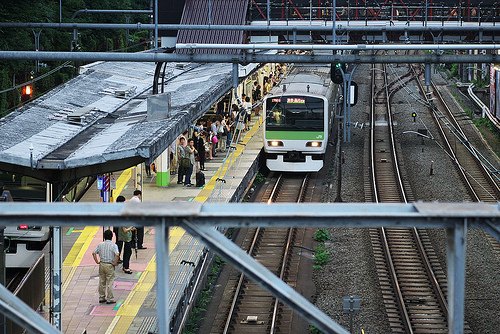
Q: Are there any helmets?
A: No, there are no helmets.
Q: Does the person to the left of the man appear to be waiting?
A: Yes, the person is waiting.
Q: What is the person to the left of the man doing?
A: The person is waiting.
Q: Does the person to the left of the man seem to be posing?
A: No, the person is waiting.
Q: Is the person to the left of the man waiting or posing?
A: The person is waiting.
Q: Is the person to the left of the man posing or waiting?
A: The person is waiting.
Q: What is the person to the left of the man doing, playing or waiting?
A: The person is waiting.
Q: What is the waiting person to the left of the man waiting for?
A: The person is waiting for the train.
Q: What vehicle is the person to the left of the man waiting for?
A: The person is waiting for the train.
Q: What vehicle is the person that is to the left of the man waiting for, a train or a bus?
A: The person is waiting for a train.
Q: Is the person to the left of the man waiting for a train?
A: Yes, the person is waiting for a train.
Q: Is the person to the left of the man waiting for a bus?
A: No, the person is waiting for a train.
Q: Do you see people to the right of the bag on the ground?
A: No, the person is to the left of the bag.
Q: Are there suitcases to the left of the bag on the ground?
A: No, there is a person to the left of the bag.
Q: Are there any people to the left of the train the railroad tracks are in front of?
A: Yes, there is a person to the left of the train.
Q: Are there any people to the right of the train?
A: No, the person is to the left of the train.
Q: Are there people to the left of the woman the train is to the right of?
A: Yes, there is a person to the left of the woman.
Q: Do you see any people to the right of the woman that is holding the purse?
A: No, the person is to the left of the woman.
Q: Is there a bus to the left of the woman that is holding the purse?
A: No, there is a person to the left of the woman.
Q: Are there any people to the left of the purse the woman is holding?
A: Yes, there is a person to the left of the purse.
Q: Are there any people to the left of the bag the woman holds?
A: Yes, there is a person to the left of the purse.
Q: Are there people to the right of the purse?
A: No, the person is to the left of the purse.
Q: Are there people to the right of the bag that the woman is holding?
A: No, the person is to the left of the purse.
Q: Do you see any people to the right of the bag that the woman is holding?
A: No, the person is to the left of the purse.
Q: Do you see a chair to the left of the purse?
A: No, there is a person to the left of the purse.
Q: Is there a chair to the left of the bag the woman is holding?
A: No, there is a person to the left of the purse.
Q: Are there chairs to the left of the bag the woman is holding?
A: No, there is a person to the left of the purse.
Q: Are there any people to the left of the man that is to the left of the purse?
A: Yes, there is a person to the left of the man.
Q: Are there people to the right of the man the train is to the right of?
A: No, the person is to the left of the man.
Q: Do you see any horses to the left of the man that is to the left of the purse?
A: No, there is a person to the left of the man.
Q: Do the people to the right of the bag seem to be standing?
A: Yes, the people are standing.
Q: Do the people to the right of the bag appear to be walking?
A: No, the people are standing.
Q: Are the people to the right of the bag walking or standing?
A: The people are standing.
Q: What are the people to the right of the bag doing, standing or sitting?
A: The people are standing.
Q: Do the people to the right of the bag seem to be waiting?
A: Yes, the people are waiting.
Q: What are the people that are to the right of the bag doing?
A: The people are waiting.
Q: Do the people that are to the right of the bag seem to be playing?
A: No, the people are waiting.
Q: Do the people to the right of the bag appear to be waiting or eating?
A: The people are waiting.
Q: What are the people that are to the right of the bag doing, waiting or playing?
A: The people are waiting.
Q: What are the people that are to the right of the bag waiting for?
A: The people are waiting for the train.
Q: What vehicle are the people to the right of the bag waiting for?
A: The people are waiting for the train.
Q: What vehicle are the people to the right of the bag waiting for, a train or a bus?
A: The people are waiting for a train.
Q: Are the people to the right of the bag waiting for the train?
A: Yes, the people are waiting for the train.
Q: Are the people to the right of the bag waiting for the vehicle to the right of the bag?
A: Yes, the people are waiting for the train.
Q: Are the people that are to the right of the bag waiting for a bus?
A: No, the people are waiting for the train.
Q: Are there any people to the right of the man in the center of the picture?
A: Yes, there are people to the right of the man.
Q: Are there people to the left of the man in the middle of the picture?
A: No, the people are to the right of the man.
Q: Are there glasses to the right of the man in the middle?
A: No, there are people to the right of the man.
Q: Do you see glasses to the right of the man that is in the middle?
A: No, there are people to the right of the man.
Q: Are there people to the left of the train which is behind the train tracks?
A: Yes, there are people to the left of the train.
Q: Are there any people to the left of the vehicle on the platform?
A: Yes, there are people to the left of the train.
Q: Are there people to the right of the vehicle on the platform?
A: No, the people are to the left of the train.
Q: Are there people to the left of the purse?
A: Yes, there are people to the left of the purse.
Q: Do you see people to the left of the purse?
A: Yes, there are people to the left of the purse.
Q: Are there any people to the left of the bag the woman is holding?
A: Yes, there are people to the left of the purse.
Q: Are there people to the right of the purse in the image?
A: No, the people are to the left of the purse.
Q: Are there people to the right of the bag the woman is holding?
A: No, the people are to the left of the purse.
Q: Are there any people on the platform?
A: Yes, there are people on the platform.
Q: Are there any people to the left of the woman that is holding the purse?
A: Yes, there are people to the left of the woman.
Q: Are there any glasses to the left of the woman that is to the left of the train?
A: No, there are people to the left of the woman.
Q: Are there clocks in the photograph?
A: No, there are no clocks.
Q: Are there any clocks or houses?
A: No, there are no clocks or houses.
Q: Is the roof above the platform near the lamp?
A: Yes, the roof is above the platform.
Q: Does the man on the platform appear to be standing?
A: Yes, the man is standing.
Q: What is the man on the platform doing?
A: The man is standing.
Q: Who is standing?
A: The man is standing.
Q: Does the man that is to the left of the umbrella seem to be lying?
A: No, the man is standing.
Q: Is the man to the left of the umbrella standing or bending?
A: The man is standing.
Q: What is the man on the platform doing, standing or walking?
A: The man is standing.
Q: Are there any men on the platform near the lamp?
A: Yes, there is a man on the platform.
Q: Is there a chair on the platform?
A: No, there is a man on the platform.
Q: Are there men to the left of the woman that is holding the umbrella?
A: Yes, there is a man to the left of the woman.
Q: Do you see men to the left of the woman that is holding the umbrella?
A: Yes, there is a man to the left of the woman.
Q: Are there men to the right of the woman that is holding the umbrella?
A: No, the man is to the left of the woman.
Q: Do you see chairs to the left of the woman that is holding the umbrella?
A: No, there is a man to the left of the woman.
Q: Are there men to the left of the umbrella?
A: Yes, there is a man to the left of the umbrella.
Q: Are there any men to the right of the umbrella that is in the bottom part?
A: No, the man is to the left of the umbrella.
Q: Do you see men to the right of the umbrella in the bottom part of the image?
A: No, the man is to the left of the umbrella.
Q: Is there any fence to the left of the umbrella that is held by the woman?
A: No, there is a man to the left of the umbrella.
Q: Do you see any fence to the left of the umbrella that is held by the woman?
A: No, there is a man to the left of the umbrella.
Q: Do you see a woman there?
A: Yes, there is a woman.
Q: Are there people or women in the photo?
A: Yes, there is a woman.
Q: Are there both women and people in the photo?
A: Yes, there are both a woman and people.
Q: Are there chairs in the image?
A: No, there are no chairs.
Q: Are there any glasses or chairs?
A: No, there are no chairs or glasses.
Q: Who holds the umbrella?
A: The woman holds the umbrella.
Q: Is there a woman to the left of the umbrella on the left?
A: Yes, there is a woman to the left of the umbrella.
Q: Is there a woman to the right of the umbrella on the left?
A: No, the woman is to the left of the umbrella.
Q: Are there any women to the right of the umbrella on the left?
A: No, the woman is to the left of the umbrella.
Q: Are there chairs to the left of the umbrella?
A: No, there is a woman to the left of the umbrella.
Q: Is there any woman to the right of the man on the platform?
A: Yes, there is a woman to the right of the man.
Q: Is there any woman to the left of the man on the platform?
A: No, the woman is to the right of the man.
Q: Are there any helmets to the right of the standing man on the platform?
A: No, there is a woman to the right of the man.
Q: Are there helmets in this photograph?
A: No, there are no helmets.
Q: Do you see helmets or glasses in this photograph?
A: No, there are no helmets or glasses.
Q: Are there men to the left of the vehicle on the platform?
A: Yes, there is a man to the left of the train.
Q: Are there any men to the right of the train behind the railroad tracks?
A: No, the man is to the left of the train.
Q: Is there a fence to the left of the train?
A: No, there is a man to the left of the train.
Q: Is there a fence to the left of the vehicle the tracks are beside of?
A: No, there is a man to the left of the train.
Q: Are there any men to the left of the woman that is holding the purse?
A: Yes, there is a man to the left of the woman.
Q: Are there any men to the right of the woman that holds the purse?
A: No, the man is to the left of the woman.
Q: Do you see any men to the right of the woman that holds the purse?
A: No, the man is to the left of the woman.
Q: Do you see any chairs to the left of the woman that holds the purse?
A: No, there is a man to the left of the woman.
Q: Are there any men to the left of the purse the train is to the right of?
A: Yes, there is a man to the left of the purse.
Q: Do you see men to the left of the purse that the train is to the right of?
A: Yes, there is a man to the left of the purse.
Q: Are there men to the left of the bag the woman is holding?
A: Yes, there is a man to the left of the purse.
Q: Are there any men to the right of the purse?
A: No, the man is to the left of the purse.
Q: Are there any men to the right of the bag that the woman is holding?
A: No, the man is to the left of the purse.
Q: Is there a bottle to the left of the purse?
A: No, there is a man to the left of the purse.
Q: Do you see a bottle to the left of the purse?
A: No, there is a man to the left of the purse.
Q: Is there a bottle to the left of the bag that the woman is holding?
A: No, there is a man to the left of the purse.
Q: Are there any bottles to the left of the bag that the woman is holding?
A: No, there is a man to the left of the purse.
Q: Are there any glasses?
A: No, there are no glasses.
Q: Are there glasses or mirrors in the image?
A: No, there are no glasses or mirrors.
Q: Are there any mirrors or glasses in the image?
A: No, there are no glasses or mirrors.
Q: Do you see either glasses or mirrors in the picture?
A: No, there are no glasses or mirrors.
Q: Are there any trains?
A: Yes, there is a train.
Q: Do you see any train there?
A: Yes, there is a train.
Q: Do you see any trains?
A: Yes, there is a train.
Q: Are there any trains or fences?
A: Yes, there is a train.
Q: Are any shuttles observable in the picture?
A: No, there are no shuttles.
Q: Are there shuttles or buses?
A: No, there are no shuttles or buses.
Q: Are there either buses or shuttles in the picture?
A: No, there are no shuttles or buses.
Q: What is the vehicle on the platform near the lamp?
A: The vehicle is a train.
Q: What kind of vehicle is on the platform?
A: The vehicle is a train.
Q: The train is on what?
A: The train is on the platform.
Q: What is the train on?
A: The train is on the platform.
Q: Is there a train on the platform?
A: Yes, there is a train on the platform.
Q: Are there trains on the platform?
A: Yes, there is a train on the platform.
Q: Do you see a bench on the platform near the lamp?
A: No, there is a train on the platform.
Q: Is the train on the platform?
A: Yes, the train is on the platform.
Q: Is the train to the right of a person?
A: Yes, the train is to the right of a person.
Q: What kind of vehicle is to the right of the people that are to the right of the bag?
A: The vehicle is a train.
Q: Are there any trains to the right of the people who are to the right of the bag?
A: Yes, there is a train to the right of the people.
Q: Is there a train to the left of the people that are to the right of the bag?
A: No, the train is to the right of the people.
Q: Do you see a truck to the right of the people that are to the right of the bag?
A: No, there is a train to the right of the people.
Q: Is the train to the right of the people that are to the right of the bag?
A: Yes, the train is to the right of the people.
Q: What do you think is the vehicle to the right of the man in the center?
A: The vehicle is a train.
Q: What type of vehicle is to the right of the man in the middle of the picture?
A: The vehicle is a train.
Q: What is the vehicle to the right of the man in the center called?
A: The vehicle is a train.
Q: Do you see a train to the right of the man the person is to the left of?
A: Yes, there is a train to the right of the man.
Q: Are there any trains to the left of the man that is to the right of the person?
A: No, the train is to the right of the man.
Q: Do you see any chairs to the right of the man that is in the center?
A: No, there is a train to the right of the man.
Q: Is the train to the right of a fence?
A: No, the train is to the right of the man.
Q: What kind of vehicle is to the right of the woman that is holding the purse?
A: The vehicle is a train.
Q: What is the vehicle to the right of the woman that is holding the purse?
A: The vehicle is a train.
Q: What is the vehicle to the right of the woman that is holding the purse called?
A: The vehicle is a train.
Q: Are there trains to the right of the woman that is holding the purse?
A: Yes, there is a train to the right of the woman.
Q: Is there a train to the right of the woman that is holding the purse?
A: Yes, there is a train to the right of the woman.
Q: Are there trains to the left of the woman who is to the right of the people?
A: No, the train is to the right of the woman.